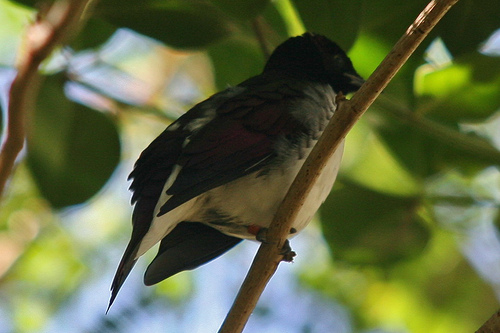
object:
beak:
[346, 74, 362, 95]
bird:
[102, 31, 371, 319]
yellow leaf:
[0, 218, 91, 331]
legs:
[258, 221, 303, 267]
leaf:
[24, 70, 120, 210]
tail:
[105, 234, 142, 314]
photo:
[2, 2, 499, 329]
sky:
[193, 234, 346, 331]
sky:
[55, 300, 98, 328]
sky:
[463, 235, 498, 258]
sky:
[118, 33, 138, 49]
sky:
[0, 308, 10, 329]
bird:
[105, 23, 376, 317]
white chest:
[326, 148, 345, 183]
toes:
[290, 249, 297, 258]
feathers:
[294, 42, 306, 59]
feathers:
[181, 130, 250, 212]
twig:
[210, 243, 293, 331]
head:
[266, 26, 366, 92]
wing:
[158, 85, 293, 219]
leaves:
[382, 107, 500, 182]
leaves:
[423, 2, 498, 58]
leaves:
[316, 179, 431, 279]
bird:
[94, 27, 372, 312]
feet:
[260, 225, 296, 261]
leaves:
[109, 1, 234, 56]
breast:
[266, 101, 346, 234]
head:
[267, 24, 371, 102]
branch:
[1, 3, 86, 79]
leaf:
[446, 75, 499, 116]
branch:
[368, 9, 449, 96]